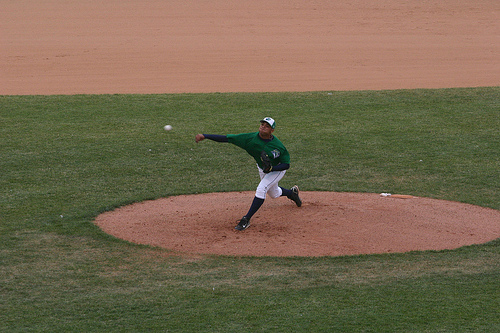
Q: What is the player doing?
A: Throwing a ball.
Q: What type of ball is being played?
A: Baseball.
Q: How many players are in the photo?
A: One.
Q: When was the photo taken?
A: During a game.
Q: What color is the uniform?
A: Green.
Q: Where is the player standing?
A: On the pitcher's mound.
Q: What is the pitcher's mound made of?
A: Dirt.